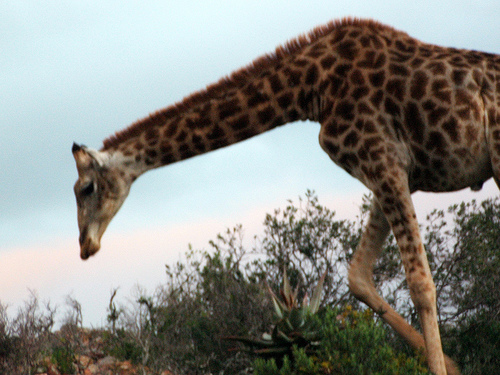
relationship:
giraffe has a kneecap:
[72, 17, 500, 375] [347, 272, 379, 299]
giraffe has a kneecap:
[72, 17, 500, 375] [410, 283, 440, 311]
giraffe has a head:
[72, 17, 500, 375] [71, 141, 133, 259]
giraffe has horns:
[72, 17, 500, 375] [71, 143, 91, 169]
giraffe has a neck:
[72, 17, 500, 375] [130, 29, 322, 177]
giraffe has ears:
[72, 17, 500, 375] [71, 141, 103, 173]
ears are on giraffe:
[71, 141, 103, 173] [72, 17, 500, 375]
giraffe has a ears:
[72, 17, 500, 375] [71, 141, 101, 176]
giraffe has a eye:
[72, 17, 500, 375] [79, 180, 95, 198]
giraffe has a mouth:
[72, 17, 500, 375] [84, 236, 92, 258]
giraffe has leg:
[72, 17, 500, 375] [348, 192, 462, 374]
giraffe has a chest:
[72, 17, 500, 375] [315, 118, 367, 190]